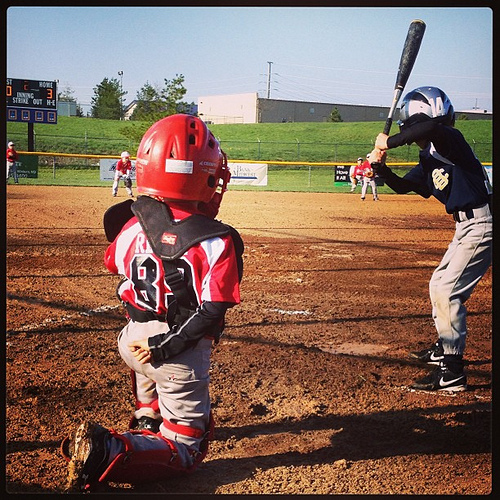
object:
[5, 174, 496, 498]
field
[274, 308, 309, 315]
white line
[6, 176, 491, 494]
ground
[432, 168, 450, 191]
logo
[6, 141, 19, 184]
person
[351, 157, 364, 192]
person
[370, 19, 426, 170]
bat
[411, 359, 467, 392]
sneakers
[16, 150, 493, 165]
yellow border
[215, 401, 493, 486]
shadow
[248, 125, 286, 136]
grass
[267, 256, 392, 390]
dirt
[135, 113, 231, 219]
helmet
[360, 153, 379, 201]
person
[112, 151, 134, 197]
person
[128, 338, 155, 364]
hand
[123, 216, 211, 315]
back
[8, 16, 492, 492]
game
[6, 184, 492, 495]
earth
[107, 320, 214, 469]
pants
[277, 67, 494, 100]
power lines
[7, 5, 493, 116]
sky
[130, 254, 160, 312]
number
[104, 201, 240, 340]
jersey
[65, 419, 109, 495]
cleat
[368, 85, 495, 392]
person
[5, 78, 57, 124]
board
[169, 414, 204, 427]
stripe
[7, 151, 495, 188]
fence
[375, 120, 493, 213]
shirt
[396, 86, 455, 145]
helmet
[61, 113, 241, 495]
people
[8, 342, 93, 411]
dirt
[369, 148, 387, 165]
hands